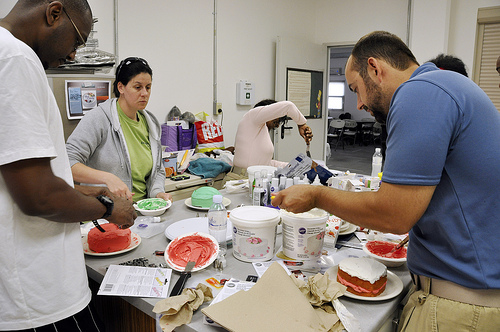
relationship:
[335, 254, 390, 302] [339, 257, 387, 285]
cake with frosting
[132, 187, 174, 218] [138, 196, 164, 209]
bowl with icing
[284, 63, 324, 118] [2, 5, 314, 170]
bulletin board on wall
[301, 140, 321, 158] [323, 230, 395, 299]
knife used cakes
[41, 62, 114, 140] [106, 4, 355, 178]
board on wall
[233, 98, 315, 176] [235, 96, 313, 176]
woman wearing shirt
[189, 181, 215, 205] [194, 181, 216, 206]
icing on cake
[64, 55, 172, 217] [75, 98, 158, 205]
lady wearing shirt.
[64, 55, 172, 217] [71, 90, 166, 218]
lady wearing jacket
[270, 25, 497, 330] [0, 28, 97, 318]
man wearing shirt.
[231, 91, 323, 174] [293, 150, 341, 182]
woman frosting cake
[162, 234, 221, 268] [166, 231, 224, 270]
frosting on plate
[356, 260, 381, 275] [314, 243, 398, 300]
frosting on cake